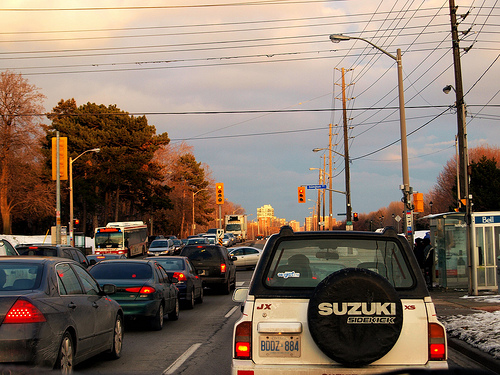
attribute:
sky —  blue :
[0, 6, 498, 198]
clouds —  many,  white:
[3, 6, 155, 51]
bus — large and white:
[85, 220, 122, 245]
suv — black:
[157, 223, 229, 267]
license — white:
[244, 324, 304, 375]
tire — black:
[319, 265, 399, 375]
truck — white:
[219, 238, 453, 375]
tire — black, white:
[311, 267, 399, 363]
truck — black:
[253, 231, 445, 370]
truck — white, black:
[228, 229, 453, 370]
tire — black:
[303, 270, 404, 363]